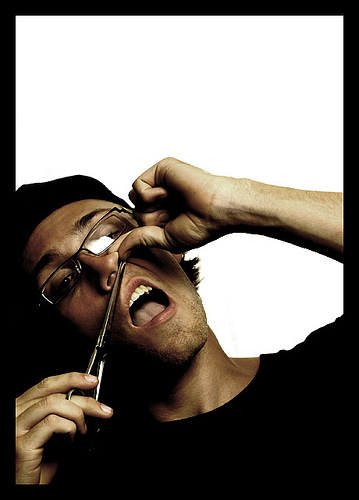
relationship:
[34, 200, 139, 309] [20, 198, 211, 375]
glasses on a man's face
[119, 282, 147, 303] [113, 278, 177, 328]
teeth in mouth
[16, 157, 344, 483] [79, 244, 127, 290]
man clearing nose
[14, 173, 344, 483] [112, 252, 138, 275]
man trimming h nose hairs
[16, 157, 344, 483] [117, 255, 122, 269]
man cutting nose hairs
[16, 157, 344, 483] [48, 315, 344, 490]
man wearing shirt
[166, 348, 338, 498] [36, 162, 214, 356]
shirt on man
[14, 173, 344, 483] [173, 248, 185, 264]
man hair behind ear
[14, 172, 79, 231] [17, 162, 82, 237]
beret on head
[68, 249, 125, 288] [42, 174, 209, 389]
nose on man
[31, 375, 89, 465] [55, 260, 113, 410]
hand holding scissors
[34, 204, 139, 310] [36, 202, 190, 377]
glasses on face